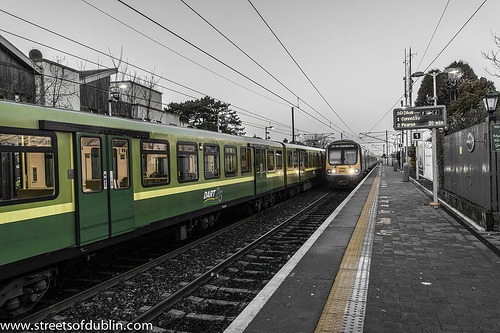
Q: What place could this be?
A: It is a walkway.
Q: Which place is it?
A: It is a walkway.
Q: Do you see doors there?
A: Yes, there are doors.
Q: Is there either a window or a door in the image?
A: Yes, there are doors.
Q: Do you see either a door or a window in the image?
A: Yes, there are doors.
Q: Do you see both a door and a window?
A: Yes, there are both a door and a window.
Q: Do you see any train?
A: Yes, there is a train.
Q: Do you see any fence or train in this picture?
A: Yes, there is a train.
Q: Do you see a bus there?
A: No, there are no buses.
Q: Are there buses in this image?
A: No, there are no buses.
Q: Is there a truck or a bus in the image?
A: No, there are no buses or trucks.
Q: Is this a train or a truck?
A: This is a train.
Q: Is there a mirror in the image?
A: No, there are no mirrors.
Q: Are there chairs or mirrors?
A: No, there are no mirrors or chairs.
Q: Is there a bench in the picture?
A: No, there are no benches.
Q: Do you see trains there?
A: Yes, there is a train.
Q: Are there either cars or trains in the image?
A: Yes, there is a train.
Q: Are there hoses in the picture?
A: No, there are no hoses.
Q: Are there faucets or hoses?
A: No, there are no hoses or faucets.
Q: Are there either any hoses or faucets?
A: No, there are no hoses or faucets.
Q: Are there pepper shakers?
A: No, there are no pepper shakers.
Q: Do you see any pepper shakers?
A: No, there are no pepper shakers.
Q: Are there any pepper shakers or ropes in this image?
A: No, there are no pepper shakers or ropes.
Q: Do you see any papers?
A: No, there are no papers.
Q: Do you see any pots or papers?
A: No, there are no papers or pots.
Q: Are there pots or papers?
A: No, there are no papers or pots.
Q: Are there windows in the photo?
A: Yes, there is a window.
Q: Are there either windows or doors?
A: Yes, there is a window.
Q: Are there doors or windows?
A: Yes, there is a window.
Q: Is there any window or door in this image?
A: Yes, there is a window.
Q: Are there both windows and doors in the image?
A: Yes, there are both a window and a door.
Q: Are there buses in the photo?
A: No, there are no buses.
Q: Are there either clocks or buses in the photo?
A: No, there are no buses or clocks.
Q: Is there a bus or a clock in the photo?
A: No, there are no buses or clocks.